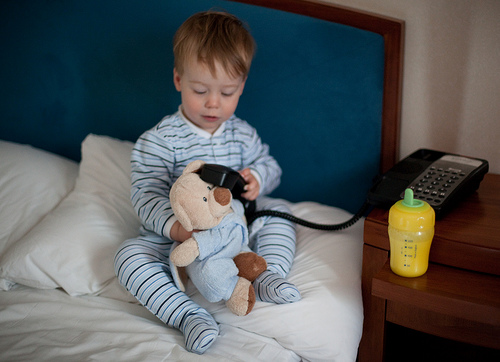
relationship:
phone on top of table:
[363, 145, 492, 217] [366, 164, 494, 359]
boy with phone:
[116, 5, 305, 349] [194, 150, 263, 238]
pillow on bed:
[0, 133, 363, 360] [2, 142, 371, 359]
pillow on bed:
[4, 141, 78, 255] [2, 142, 371, 359]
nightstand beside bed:
[360, 166, 499, 356] [2, 142, 371, 359]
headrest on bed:
[0, 2, 386, 208] [2, 142, 371, 359]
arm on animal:
[170, 228, 218, 273] [170, 159, 267, 316]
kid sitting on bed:
[112, 9, 297, 360] [2, 142, 371, 359]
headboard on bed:
[2, 4, 404, 156] [2, 142, 371, 359]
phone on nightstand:
[363, 145, 492, 217] [360, 166, 499, 356]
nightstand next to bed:
[360, 166, 499, 356] [2, 142, 371, 359]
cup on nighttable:
[388, 189, 434, 276] [359, 161, 489, 356]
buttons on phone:
[410, 167, 461, 202] [363, 145, 492, 217]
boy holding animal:
[116, 5, 305, 349] [170, 159, 267, 316]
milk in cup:
[391, 240, 430, 277] [388, 189, 434, 276]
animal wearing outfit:
[170, 159, 267, 316] [188, 189, 245, 304]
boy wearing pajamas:
[116, 5, 305, 349] [115, 110, 304, 356]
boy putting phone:
[116, 5, 305, 349] [193, 163, 258, 229]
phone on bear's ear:
[193, 163, 258, 229] [169, 160, 209, 191]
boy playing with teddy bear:
[116, 5, 305, 349] [168, 160, 268, 318]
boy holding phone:
[116, 5, 305, 349] [193, 163, 258, 229]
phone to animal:
[193, 163, 258, 229] [170, 159, 265, 313]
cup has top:
[388, 189, 434, 276] [400, 189, 420, 207]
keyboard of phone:
[413, 156, 483, 212] [363, 145, 492, 217]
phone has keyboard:
[363, 145, 492, 217] [413, 156, 483, 212]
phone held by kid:
[193, 163, 258, 229] [112, 9, 297, 360]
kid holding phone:
[112, 9, 297, 360] [193, 163, 258, 229]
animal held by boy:
[170, 159, 267, 316] [116, 5, 305, 349]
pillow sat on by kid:
[0, 133, 363, 360] [112, 9, 297, 360]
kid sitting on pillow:
[112, 9, 297, 360] [0, 133, 363, 360]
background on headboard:
[1, 0, 140, 127] [2, 4, 404, 156]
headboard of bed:
[2, 4, 404, 156] [2, 142, 371, 359]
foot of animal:
[230, 275, 255, 318] [170, 159, 267, 316]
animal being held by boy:
[170, 159, 267, 316] [116, 5, 305, 349]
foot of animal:
[234, 251, 268, 278] [170, 159, 267, 316]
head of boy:
[173, 5, 253, 134] [116, 5, 305, 349]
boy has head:
[116, 5, 305, 349] [173, 5, 253, 134]